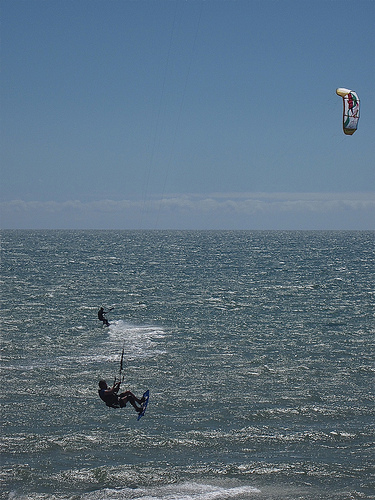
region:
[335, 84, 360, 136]
A kite in the air.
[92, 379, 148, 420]
A man wind surfing.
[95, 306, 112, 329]
A man waterskiing.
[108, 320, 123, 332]
A small white wave.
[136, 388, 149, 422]
The man's blue board.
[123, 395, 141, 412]
The man's leg.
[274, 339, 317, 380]
Part of the water.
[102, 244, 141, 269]
Part of the blue water.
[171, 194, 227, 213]
White clouds in the sky.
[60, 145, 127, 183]
Part of the blue sky.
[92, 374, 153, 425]
Man in the air above water.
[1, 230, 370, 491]
Vast blue ocean.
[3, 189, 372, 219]
Fluffy gray clouds in the sky.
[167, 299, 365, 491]
Waves on top of water.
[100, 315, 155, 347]
White water splashing.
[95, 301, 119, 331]
Man kite boarding on water.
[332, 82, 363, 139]
Large kite in the air.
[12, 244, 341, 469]
Waves caused by the wind.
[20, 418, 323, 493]
Sun reflecting on water.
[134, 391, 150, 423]
Kite board on man's feet.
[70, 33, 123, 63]
Blue skies in the background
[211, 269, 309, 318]
calm sea waters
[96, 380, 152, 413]
a man surfing on the ocean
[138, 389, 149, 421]
a blue surfing board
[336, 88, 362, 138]
a surfing balloon in the air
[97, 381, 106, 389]
the head of a man surfing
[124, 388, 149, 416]
the legs of a man surfing on the surfing board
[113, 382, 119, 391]
the hands of a man surfing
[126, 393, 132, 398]
the knee of a man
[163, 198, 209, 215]
white clouds on the horizon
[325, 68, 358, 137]
A colored kite up the sky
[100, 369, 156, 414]
A man sea sketing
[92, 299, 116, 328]
A man sea sketing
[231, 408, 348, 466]
A blue water surface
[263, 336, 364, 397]
A blue water surface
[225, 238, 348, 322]
A blue water surface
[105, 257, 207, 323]
A blue water surface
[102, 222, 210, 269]
A blue water surface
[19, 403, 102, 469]
A blue water surface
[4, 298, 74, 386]
A blue water surface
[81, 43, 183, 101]
blue skies in the background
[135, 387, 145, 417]
a blue surfing board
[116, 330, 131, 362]
a string attached to the surfing baloon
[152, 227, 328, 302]
calm sea waters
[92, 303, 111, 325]
a man surfing on the water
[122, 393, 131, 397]
the knee of a man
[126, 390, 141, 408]
the legs of a man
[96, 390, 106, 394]
the shoulder of a man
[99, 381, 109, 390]
the head of a man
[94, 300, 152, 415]
two men surfing on the water